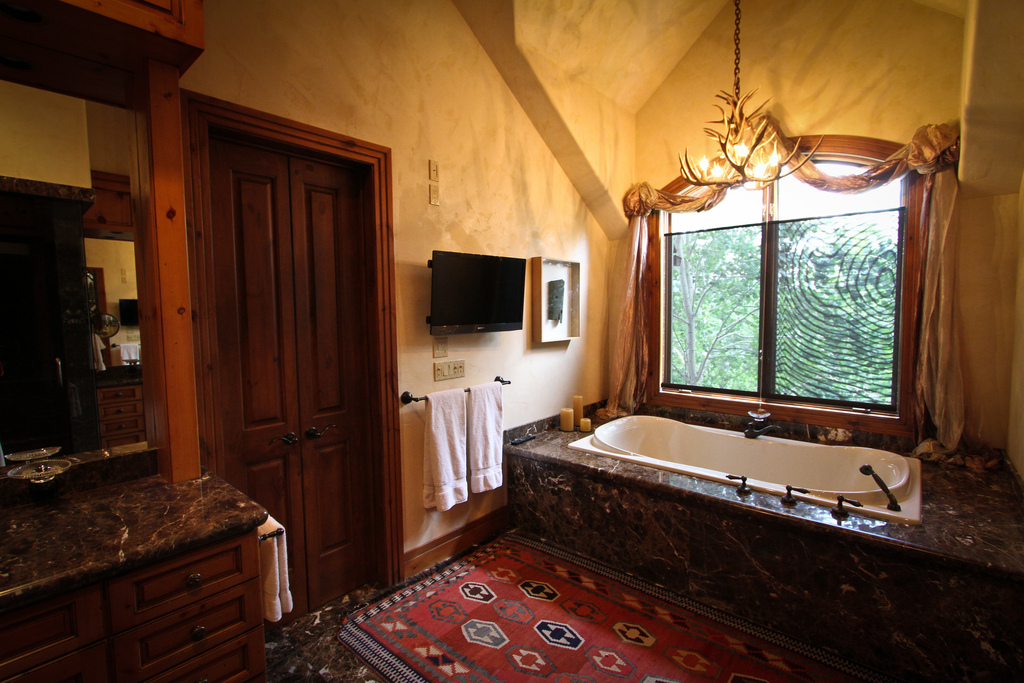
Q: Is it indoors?
A: Yes, it is indoors.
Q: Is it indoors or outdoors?
A: It is indoors.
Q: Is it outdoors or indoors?
A: It is indoors.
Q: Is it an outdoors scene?
A: No, it is indoors.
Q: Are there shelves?
A: No, there are no shelves.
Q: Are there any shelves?
A: No, there are no shelves.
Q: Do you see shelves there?
A: No, there are no shelves.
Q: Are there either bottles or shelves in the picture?
A: No, there are no shelves or bottles.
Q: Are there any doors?
A: Yes, there is a door.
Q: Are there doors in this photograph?
A: Yes, there is a door.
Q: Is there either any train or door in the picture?
A: Yes, there is a door.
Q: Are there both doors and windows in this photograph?
A: Yes, there are both a door and windows.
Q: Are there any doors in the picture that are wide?
A: Yes, there is a wide door.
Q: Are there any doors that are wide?
A: Yes, there is a door that is wide.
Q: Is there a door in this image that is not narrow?
A: Yes, there is a wide door.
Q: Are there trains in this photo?
A: No, there are no trains.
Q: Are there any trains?
A: No, there are no trains.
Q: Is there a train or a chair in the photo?
A: No, there are no trains or chairs.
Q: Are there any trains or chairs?
A: No, there are no trains or chairs.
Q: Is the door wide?
A: Yes, the door is wide.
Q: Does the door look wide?
A: Yes, the door is wide.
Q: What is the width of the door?
A: The door is wide.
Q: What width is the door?
A: The door is wide.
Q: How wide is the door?
A: The door is wide.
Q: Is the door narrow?
A: No, the door is wide.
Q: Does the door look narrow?
A: No, the door is wide.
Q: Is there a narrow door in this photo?
A: No, there is a door but it is wide.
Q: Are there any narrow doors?
A: No, there is a door but it is wide.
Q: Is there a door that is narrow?
A: No, there is a door but it is wide.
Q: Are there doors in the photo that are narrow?
A: No, there is a door but it is wide.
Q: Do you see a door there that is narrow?
A: No, there is a door but it is wide.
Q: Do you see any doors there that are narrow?
A: No, there is a door but it is wide.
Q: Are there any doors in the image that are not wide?
A: No, there is a door but it is wide.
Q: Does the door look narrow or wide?
A: The door is wide.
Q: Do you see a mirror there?
A: Yes, there is a mirror.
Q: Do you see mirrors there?
A: Yes, there is a mirror.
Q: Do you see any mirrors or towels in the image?
A: Yes, there is a mirror.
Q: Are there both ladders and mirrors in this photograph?
A: No, there is a mirror but no ladders.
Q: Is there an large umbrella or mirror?
A: Yes, there is a large mirror.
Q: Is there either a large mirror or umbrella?
A: Yes, there is a large mirror.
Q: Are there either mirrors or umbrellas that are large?
A: Yes, the mirror is large.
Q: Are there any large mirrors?
A: Yes, there is a large mirror.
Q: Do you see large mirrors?
A: Yes, there is a large mirror.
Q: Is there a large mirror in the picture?
A: Yes, there is a large mirror.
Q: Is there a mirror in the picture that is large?
A: Yes, there is a mirror that is large.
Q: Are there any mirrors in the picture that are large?
A: Yes, there is a mirror that is large.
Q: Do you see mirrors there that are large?
A: Yes, there is a mirror that is large.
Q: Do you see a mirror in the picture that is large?
A: Yes, there is a mirror that is large.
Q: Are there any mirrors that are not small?
A: Yes, there is a large mirror.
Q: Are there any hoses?
A: No, there are no hoses.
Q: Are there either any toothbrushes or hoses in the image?
A: No, there are no hoses or toothbrushes.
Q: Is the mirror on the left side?
A: Yes, the mirror is on the left of the image.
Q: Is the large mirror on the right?
A: No, the mirror is on the left of the image.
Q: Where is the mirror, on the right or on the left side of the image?
A: The mirror is on the left of the image.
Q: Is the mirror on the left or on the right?
A: The mirror is on the left of the image.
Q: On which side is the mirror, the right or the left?
A: The mirror is on the left of the image.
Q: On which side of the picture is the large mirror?
A: The mirror is on the left of the image.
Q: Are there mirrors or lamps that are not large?
A: No, there is a mirror but it is large.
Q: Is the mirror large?
A: Yes, the mirror is large.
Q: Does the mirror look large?
A: Yes, the mirror is large.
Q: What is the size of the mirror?
A: The mirror is large.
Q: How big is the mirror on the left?
A: The mirror is large.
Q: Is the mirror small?
A: No, the mirror is large.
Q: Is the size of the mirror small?
A: No, the mirror is large.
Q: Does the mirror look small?
A: No, the mirror is large.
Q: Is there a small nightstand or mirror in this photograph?
A: No, there is a mirror but it is large.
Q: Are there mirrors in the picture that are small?
A: No, there is a mirror but it is large.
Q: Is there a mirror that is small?
A: No, there is a mirror but it is large.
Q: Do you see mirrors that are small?
A: No, there is a mirror but it is large.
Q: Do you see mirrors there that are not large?
A: No, there is a mirror but it is large.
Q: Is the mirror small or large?
A: The mirror is large.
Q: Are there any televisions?
A: Yes, there is a television.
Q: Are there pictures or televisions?
A: Yes, there is a television.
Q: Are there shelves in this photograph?
A: No, there are no shelves.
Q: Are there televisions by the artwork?
A: Yes, there is a television by the artwork.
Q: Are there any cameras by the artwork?
A: No, there is a television by the artwork.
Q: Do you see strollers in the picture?
A: No, there are no strollers.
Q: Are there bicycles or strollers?
A: No, there are no strollers or bicycles.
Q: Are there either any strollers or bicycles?
A: No, there are no strollers or bicycles.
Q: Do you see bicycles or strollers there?
A: No, there are no strollers or bicycles.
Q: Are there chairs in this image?
A: No, there are no chairs.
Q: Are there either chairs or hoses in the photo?
A: No, there are no chairs or hoses.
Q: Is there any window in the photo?
A: Yes, there is a window.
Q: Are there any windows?
A: Yes, there is a window.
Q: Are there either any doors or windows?
A: Yes, there is a window.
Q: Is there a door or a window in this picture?
A: Yes, there is a window.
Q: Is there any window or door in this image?
A: Yes, there is a window.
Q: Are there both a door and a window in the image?
A: Yes, there are both a window and a door.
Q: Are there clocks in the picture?
A: No, there are no clocks.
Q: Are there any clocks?
A: No, there are no clocks.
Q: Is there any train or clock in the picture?
A: No, there are no clocks or trains.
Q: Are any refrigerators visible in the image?
A: No, there are no refrigerators.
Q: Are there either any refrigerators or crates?
A: No, there are no refrigerators or crates.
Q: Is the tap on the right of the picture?
A: Yes, the tap is on the right of the image.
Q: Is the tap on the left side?
A: No, the tap is on the right of the image.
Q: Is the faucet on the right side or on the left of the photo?
A: The faucet is on the right of the image.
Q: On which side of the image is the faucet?
A: The faucet is on the right of the image.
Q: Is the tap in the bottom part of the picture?
A: Yes, the tap is in the bottom of the image.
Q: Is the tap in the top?
A: No, the tap is in the bottom of the image.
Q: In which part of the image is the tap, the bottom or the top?
A: The tap is in the bottom of the image.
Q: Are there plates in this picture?
A: No, there are no plates.